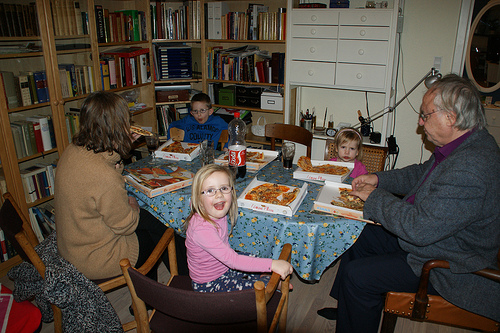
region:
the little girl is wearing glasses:
[200, 183, 232, 197]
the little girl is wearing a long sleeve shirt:
[186, 213, 275, 285]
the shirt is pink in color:
[188, 212, 273, 286]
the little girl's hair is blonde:
[192, 163, 238, 228]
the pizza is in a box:
[247, 177, 298, 210]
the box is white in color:
[236, 176, 309, 216]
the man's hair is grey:
[418, 73, 481, 152]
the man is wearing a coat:
[369, 140, 497, 295]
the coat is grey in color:
[374, 134, 499, 309]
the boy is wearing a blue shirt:
[172, 116, 242, 139]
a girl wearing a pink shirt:
[176, 211, 256, 276]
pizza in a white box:
[238, 173, 315, 215]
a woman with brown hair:
[71, 96, 148, 159]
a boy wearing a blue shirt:
[179, 92, 234, 151]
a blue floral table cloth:
[268, 208, 343, 270]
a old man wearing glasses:
[411, 87, 486, 151]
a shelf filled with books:
[93, 31, 178, 103]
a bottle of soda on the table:
[223, 119, 265, 180]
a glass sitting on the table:
[276, 133, 309, 173]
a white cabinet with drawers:
[287, 30, 397, 91]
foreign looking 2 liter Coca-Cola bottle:
[225, 108, 248, 181]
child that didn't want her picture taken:
[332, 127, 363, 159]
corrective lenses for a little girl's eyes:
[195, 183, 235, 199]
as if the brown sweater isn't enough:
[4, 226, 125, 331]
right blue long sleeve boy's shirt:
[163, 112, 230, 154]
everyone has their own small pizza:
[122, 137, 387, 228]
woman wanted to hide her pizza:
[123, 159, 196, 199]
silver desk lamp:
[337, 67, 442, 134]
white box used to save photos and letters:
[259, 89, 284, 111]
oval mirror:
[463, 0, 498, 95]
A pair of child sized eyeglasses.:
[191, 185, 240, 196]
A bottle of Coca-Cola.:
[229, 111, 249, 180]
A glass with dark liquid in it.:
[279, 137, 298, 170]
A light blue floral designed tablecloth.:
[117, 142, 378, 291]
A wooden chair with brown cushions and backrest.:
[116, 223, 297, 330]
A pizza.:
[241, 177, 306, 221]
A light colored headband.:
[336, 126, 363, 145]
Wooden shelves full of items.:
[1, 2, 286, 276]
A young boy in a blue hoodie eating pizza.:
[164, 92, 232, 159]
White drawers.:
[286, 9, 395, 91]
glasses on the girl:
[200, 185, 232, 193]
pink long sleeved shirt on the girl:
[183, 212, 271, 282]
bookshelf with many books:
[1, 1, 289, 241]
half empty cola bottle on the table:
[226, 109, 246, 179]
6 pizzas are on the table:
[129, 138, 383, 224]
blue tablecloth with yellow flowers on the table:
[126, 147, 366, 281]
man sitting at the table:
[318, 72, 498, 332]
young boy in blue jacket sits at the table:
[164, 93, 228, 153]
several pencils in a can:
[297, 105, 316, 134]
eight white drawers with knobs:
[286, 6, 397, 93]